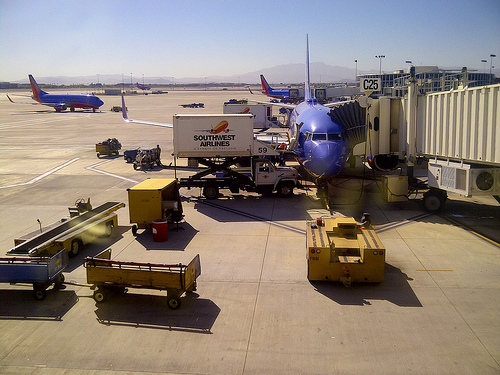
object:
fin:
[28, 73, 48, 95]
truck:
[171, 112, 299, 203]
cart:
[0, 248, 69, 301]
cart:
[82, 247, 200, 310]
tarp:
[0, 58, 499, 374]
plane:
[210, 119, 229, 134]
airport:
[0, 50, 500, 375]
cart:
[95, 138, 122, 159]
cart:
[13, 197, 119, 255]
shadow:
[91, 290, 221, 334]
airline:
[193, 134, 236, 146]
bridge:
[326, 65, 499, 216]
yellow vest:
[126, 177, 177, 223]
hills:
[8, 61, 500, 83]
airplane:
[135, 82, 149, 90]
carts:
[124, 148, 152, 164]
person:
[155, 144, 160, 160]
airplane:
[5, 73, 105, 112]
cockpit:
[301, 124, 343, 149]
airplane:
[120, 32, 358, 180]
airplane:
[259, 74, 290, 98]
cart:
[126, 178, 186, 237]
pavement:
[0, 86, 500, 373]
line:
[0, 157, 79, 190]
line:
[84, 158, 138, 183]